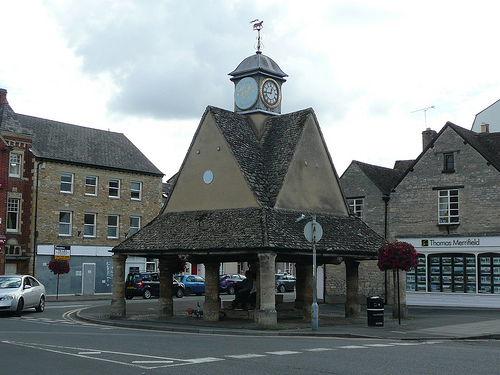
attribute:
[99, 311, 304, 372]
road — paved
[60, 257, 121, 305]
door — gray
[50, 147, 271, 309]
building — brown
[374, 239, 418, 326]
tree — young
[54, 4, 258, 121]
rain cloud — grey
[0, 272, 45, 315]
car — silver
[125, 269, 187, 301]
car — small, black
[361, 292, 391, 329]
can — black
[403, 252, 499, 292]
window — display window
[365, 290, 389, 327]
receptical — trash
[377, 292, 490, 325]
sidewalk — concrete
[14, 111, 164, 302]
building — brick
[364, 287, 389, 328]
can — black, garbage can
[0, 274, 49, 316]
car — white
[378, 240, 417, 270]
leaves — red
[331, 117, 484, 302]
building — brown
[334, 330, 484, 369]
road — paved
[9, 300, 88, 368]
road — paved